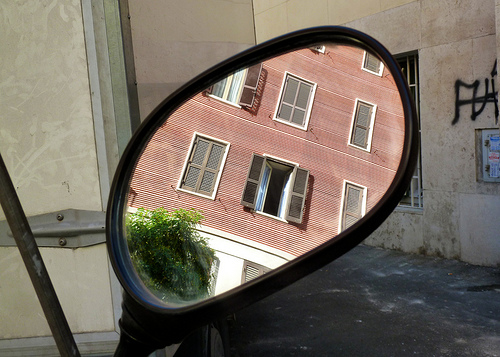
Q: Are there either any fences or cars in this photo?
A: No, there are no cars or fences.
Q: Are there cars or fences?
A: No, there are no cars or fences.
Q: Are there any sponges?
A: No, there are no sponges.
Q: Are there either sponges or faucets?
A: No, there are no sponges or faucets.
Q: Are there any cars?
A: No, there are no cars.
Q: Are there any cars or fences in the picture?
A: No, there are no cars or fences.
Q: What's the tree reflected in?
A: The tree is reflected in the mirror.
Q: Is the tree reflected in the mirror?
A: Yes, the tree is reflected in the mirror.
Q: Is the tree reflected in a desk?
A: No, the tree is reflected in the mirror.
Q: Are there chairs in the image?
A: No, there are no chairs.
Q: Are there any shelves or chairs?
A: No, there are no chairs or shelves.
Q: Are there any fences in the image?
A: No, there are no fences.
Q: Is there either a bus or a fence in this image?
A: No, there are no fences or buses.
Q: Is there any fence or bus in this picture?
A: No, there are no fences or buses.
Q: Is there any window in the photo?
A: Yes, there is a window.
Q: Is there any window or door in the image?
A: Yes, there is a window.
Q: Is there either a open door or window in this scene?
A: Yes, there is an open window.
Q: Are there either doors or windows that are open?
A: Yes, the window is open.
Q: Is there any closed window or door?
A: Yes, there is a closed window.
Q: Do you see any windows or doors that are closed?
A: Yes, the window is closed.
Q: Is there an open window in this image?
A: Yes, there is an open window.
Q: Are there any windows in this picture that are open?
A: Yes, there is a window that is open.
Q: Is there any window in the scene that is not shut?
A: Yes, there is a open window.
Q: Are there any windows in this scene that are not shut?
A: Yes, there is a open window.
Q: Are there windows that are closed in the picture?
A: Yes, there is a closed window.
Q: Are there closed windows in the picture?
A: Yes, there is a closed window.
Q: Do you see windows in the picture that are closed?
A: Yes, there is a window that is closed.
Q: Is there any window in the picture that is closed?
A: Yes, there is a window that is closed.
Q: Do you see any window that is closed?
A: Yes, there is a window that is closed.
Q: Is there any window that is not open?
A: Yes, there is an closed window.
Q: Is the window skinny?
A: Yes, the window is skinny.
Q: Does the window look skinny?
A: Yes, the window is skinny.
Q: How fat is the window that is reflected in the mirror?
A: The window is skinny.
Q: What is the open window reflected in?
A: The window is reflected in the mirror.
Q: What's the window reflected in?
A: The window is reflected in the mirror.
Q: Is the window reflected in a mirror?
A: Yes, the window is reflected in a mirror.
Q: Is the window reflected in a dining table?
A: No, the window is reflected in a mirror.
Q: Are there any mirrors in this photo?
A: Yes, there is a mirror.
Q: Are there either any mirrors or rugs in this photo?
A: Yes, there is a mirror.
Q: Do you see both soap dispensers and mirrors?
A: No, there is a mirror but no soap dispensers.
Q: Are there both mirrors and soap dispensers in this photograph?
A: No, there is a mirror but no soap dispensers.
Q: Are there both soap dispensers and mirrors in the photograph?
A: No, there is a mirror but no soap dispensers.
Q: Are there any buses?
A: No, there are no buses.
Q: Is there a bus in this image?
A: No, there are no buses.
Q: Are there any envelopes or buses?
A: No, there are no buses or envelopes.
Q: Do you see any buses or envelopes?
A: No, there are no buses or envelopes.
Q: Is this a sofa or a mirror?
A: This is a mirror.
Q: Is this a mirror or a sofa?
A: This is a mirror.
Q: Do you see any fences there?
A: No, there are no fences.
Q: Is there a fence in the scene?
A: No, there are no fences.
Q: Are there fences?
A: No, there are no fences.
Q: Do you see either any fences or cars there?
A: No, there are no fences or cars.